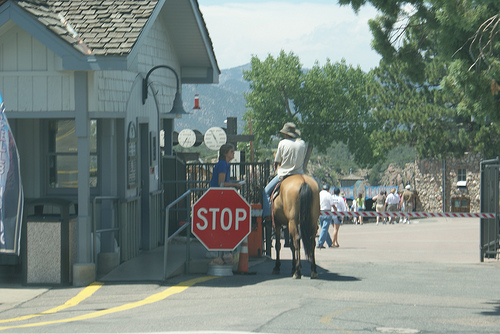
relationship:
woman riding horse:
[210, 143, 242, 187] [270, 152, 320, 279]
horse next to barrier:
[270, 152, 320, 279] [319, 210, 495, 217]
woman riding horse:
[264, 121, 308, 220] [268, 175, 321, 277]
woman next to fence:
[264, 121, 308, 220] [186, 160, 270, 245]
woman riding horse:
[210, 143, 242, 187] [265, 170, 318, 272]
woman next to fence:
[210, 143, 242, 187] [159, 187, 201, 269]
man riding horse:
[260, 120, 308, 226] [267, 149, 320, 280]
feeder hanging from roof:
[191, 93, 206, 113] [173, 52, 226, 88]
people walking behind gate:
[318, 184, 418, 262] [324, 202, 498, 227]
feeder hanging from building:
[192, 94, 201, 110] [9, 9, 240, 296]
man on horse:
[261, 122, 307, 226] [259, 172, 321, 277]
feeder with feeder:
[192, 94, 201, 110] [192, 94, 201, 110]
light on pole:
[166, 95, 186, 123] [69, 68, 91, 290]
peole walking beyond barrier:
[313, 176, 426, 261] [319, 202, 483, 222]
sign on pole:
[185, 185, 252, 257] [203, 249, 238, 274]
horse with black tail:
[270, 152, 320, 279] [298, 182, 315, 259]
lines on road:
[0, 248, 185, 332] [0, 211, 500, 333]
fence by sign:
[161, 179, 246, 281] [190, 187, 250, 254]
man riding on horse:
[261, 122, 307, 226] [268, 175, 321, 277]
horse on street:
[276, 174, 321, 279] [344, 254, 451, 311]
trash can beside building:
[19, 195, 76, 290] [98, 9, 182, 218]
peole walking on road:
[316, 184, 337, 248] [4, 211, 496, 332]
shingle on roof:
[95, 46, 103, 55] [15, 1, 150, 59]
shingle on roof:
[60, 32, 77, 44] [15, 1, 150, 59]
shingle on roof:
[35, 14, 50, 24] [15, 1, 150, 59]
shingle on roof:
[111, 23, 131, 29] [15, 1, 150, 59]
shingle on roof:
[133, 11, 149, 19] [15, 1, 150, 59]